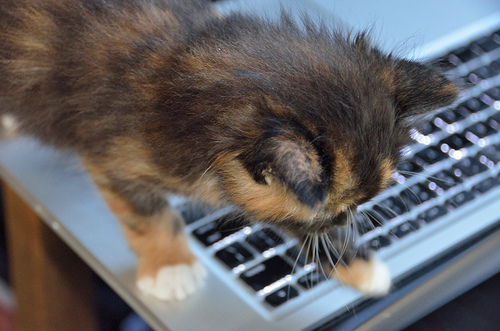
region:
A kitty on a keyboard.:
[2, 2, 460, 304]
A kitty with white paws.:
[1, 3, 466, 303]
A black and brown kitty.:
[1, 3, 469, 304]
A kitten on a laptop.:
[2, 3, 466, 303]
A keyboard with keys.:
[173, 23, 498, 308]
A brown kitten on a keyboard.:
[2, 1, 468, 303]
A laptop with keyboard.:
[6, 2, 499, 328]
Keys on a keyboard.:
[175, 25, 495, 308]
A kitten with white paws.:
[1, 1, 467, 303]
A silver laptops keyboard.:
[3, 3, 495, 327]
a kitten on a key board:
[31, 0, 481, 315]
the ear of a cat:
[235, 105, 343, 205]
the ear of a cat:
[389, 50, 460, 121]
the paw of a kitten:
[127, 240, 206, 305]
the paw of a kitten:
[338, 247, 395, 304]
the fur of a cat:
[16, 17, 66, 84]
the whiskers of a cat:
[281, 232, 347, 282]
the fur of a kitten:
[206, 35, 276, 80]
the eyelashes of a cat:
[335, 197, 368, 262]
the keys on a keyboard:
[403, 132, 496, 234]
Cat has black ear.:
[259, 149, 325, 191]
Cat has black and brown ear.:
[401, 58, 443, 113]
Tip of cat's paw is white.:
[138, 275, 210, 290]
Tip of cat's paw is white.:
[364, 260, 389, 297]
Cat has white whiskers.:
[308, 231, 335, 277]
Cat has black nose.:
[340, 207, 347, 219]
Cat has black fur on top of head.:
[278, 49, 388, 154]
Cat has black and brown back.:
[43, 9, 180, 106]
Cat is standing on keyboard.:
[103, 138, 393, 311]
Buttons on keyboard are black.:
[415, 140, 464, 202]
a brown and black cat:
[1, 0, 496, 328]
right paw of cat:
[365, 251, 401, 303]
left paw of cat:
[139, 260, 213, 305]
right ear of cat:
[386, 43, 471, 135]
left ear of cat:
[245, 103, 347, 211]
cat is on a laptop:
[2, 3, 498, 328]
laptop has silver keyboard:
[385, 27, 495, 260]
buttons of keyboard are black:
[420, 54, 494, 202]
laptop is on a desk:
[5, 139, 230, 326]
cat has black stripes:
[0, 0, 467, 294]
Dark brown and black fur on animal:
[268, 130, 335, 199]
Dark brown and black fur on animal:
[330, 129, 378, 190]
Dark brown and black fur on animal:
[355, 84, 372, 129]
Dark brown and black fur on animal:
[376, 36, 405, 101]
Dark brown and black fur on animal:
[183, 81, 249, 136]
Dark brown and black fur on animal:
[105, 126, 141, 166]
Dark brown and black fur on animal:
[123, 96, 183, 139]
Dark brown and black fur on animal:
[130, 56, 217, 114]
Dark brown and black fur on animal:
[126, 1, 197, 75]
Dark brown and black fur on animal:
[9, 33, 135, 90]